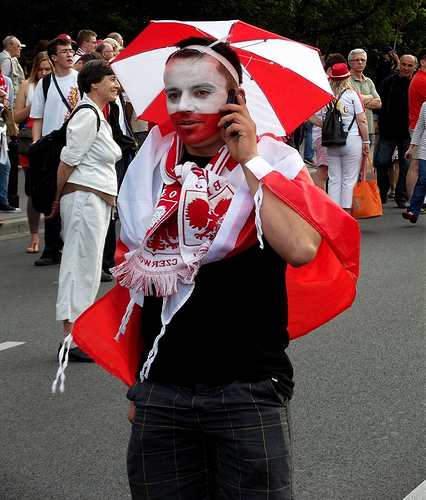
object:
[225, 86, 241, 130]
phone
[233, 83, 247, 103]
ear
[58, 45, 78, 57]
glasses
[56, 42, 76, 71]
man's face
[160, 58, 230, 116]
paint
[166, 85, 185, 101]
eyes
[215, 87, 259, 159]
hand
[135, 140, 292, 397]
black shirt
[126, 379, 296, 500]
pants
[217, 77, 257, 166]
holding phone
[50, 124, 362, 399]
flag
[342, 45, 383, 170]
man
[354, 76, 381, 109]
arm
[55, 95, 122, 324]
clothes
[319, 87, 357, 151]
her bag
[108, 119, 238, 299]
scarf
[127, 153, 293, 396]
shirt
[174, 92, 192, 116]
nose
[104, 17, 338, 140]
sunhat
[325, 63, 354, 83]
hat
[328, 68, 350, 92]
head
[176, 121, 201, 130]
lips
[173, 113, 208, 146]
paint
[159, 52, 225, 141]
face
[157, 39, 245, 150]
head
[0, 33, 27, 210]
people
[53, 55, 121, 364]
woman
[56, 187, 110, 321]
pants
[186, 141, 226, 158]
neck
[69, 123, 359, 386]
cape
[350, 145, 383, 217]
bag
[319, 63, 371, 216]
lady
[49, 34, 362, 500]
man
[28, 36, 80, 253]
man